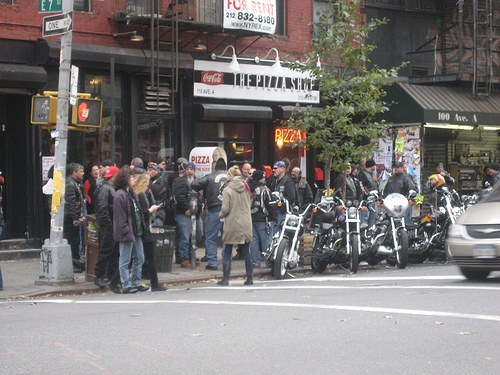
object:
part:
[206, 306, 315, 354]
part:
[254, 297, 299, 310]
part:
[351, 247, 356, 261]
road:
[8, 260, 500, 371]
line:
[24, 293, 497, 324]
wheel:
[275, 239, 289, 279]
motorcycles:
[304, 195, 377, 273]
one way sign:
[43, 10, 74, 38]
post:
[41, 2, 72, 279]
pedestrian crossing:
[32, 95, 57, 125]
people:
[112, 167, 148, 293]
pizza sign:
[189, 146, 228, 178]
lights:
[221, 45, 240, 71]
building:
[1, 0, 321, 239]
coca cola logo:
[200, 70, 223, 85]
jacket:
[219, 176, 254, 245]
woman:
[217, 165, 255, 285]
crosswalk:
[27, 272, 500, 326]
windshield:
[285, 203, 309, 223]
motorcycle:
[258, 191, 329, 279]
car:
[444, 178, 498, 282]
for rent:
[227, 0, 276, 15]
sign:
[222, 0, 277, 35]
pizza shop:
[170, 53, 327, 216]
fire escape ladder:
[142, 1, 182, 123]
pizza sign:
[275, 128, 301, 144]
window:
[274, 127, 307, 184]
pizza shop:
[234, 73, 316, 92]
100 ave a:
[196, 88, 215, 95]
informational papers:
[376, 137, 393, 157]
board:
[360, 122, 422, 218]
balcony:
[111, 2, 295, 37]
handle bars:
[272, 191, 291, 215]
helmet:
[383, 193, 409, 218]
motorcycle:
[360, 189, 417, 269]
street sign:
[34, 0, 73, 16]